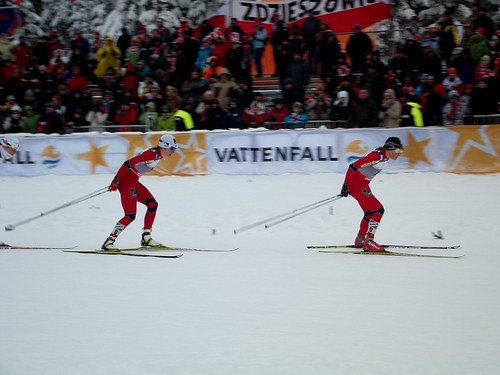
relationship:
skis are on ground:
[308, 238, 469, 264] [0, 169, 495, 369]